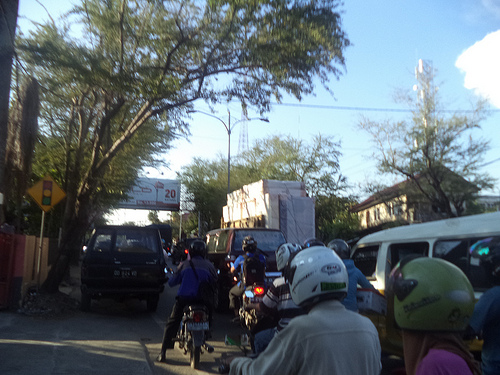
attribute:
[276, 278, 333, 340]
shirt — brown, white, striped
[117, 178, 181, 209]
billboard — white, red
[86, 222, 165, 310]
vehicle — parked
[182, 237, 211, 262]
helmet — shiny, black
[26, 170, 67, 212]
sign — yellow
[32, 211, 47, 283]
pole — metal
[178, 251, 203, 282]
strap — black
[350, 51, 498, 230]
tree — tall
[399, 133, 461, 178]
branches — bare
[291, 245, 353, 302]
helmet — white, black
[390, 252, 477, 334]
helmet — green, black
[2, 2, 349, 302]
tree — tall